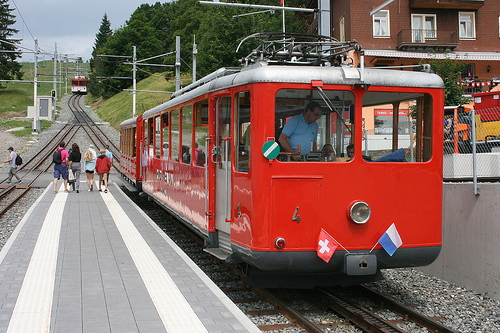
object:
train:
[103, 57, 463, 291]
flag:
[310, 225, 349, 264]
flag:
[374, 221, 405, 258]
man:
[276, 98, 325, 161]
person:
[95, 148, 113, 194]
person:
[83, 147, 98, 192]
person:
[68, 142, 84, 194]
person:
[51, 139, 72, 195]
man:
[0, 146, 28, 186]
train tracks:
[0, 90, 124, 241]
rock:
[33, 188, 40, 191]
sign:
[260, 139, 283, 160]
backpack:
[14, 154, 24, 167]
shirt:
[51, 146, 71, 167]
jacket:
[95, 155, 112, 174]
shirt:
[66, 150, 83, 164]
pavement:
[0, 175, 264, 333]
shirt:
[278, 112, 320, 156]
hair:
[87, 154, 91, 158]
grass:
[89, 68, 198, 134]